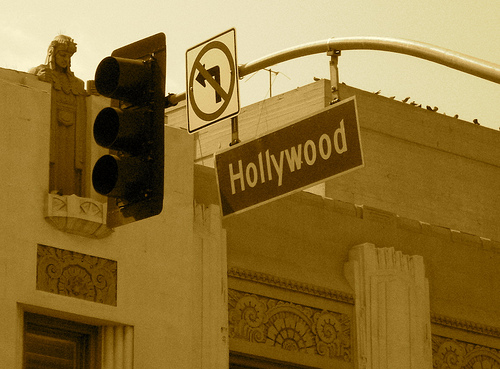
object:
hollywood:
[226, 118, 348, 194]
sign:
[213, 95, 365, 220]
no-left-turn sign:
[184, 27, 240, 134]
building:
[2, 124, 220, 368]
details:
[35, 242, 118, 308]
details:
[226, 287, 358, 368]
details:
[431, 332, 499, 369]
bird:
[472, 118, 480, 127]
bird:
[426, 105, 435, 114]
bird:
[402, 95, 411, 105]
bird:
[311, 75, 322, 82]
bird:
[372, 89, 382, 95]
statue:
[32, 34, 98, 196]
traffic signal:
[93, 33, 166, 230]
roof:
[240, 74, 498, 136]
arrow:
[195, 65, 222, 104]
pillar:
[344, 243, 433, 369]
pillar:
[195, 203, 229, 369]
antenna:
[256, 65, 288, 97]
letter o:
[302, 138, 317, 167]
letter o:
[317, 132, 332, 161]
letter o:
[247, 161, 258, 188]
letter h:
[227, 160, 246, 196]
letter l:
[256, 150, 267, 184]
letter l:
[263, 148, 273, 182]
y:
[270, 150, 285, 188]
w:
[282, 142, 303, 172]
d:
[332, 119, 348, 154]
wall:
[159, 128, 201, 357]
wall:
[241, 208, 340, 290]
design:
[226, 262, 359, 308]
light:
[94, 56, 153, 101]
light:
[92, 105, 146, 153]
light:
[90, 155, 146, 196]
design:
[310, 192, 500, 240]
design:
[43, 194, 115, 240]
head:
[47, 35, 77, 72]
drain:
[49, 107, 105, 238]